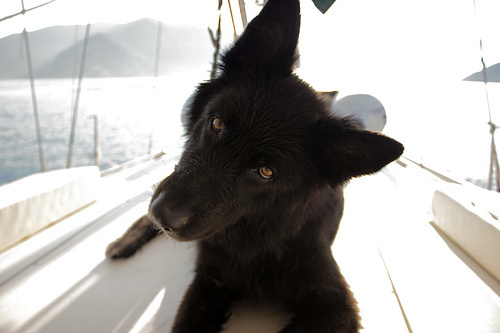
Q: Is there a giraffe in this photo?
A: No, there are no giraffes.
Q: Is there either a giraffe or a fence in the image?
A: No, there are no giraffes or fences.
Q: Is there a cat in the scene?
A: No, there are no cats.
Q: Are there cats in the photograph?
A: No, there are no cats.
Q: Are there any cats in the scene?
A: No, there are no cats.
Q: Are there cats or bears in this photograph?
A: No, there are no cats or bears.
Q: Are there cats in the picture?
A: No, there are no cats.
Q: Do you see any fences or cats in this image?
A: No, there are no cats or fences.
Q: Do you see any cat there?
A: No, there are no cats.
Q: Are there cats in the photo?
A: No, there are no cats.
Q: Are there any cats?
A: No, there are no cats.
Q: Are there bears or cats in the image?
A: No, there are no cats or bears.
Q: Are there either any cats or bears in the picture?
A: No, there are no cats or bears.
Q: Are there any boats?
A: Yes, there is a boat.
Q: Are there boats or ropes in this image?
A: Yes, there is a boat.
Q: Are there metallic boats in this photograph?
A: Yes, there is a metal boat.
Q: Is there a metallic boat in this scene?
A: Yes, there is a metal boat.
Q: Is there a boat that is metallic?
A: Yes, there is a boat that is metallic.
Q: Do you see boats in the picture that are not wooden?
A: Yes, there is a metallic boat.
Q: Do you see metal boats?
A: Yes, there is a boat that is made of metal.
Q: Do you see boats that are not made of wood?
A: Yes, there is a boat that is made of metal.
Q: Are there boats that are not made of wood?
A: Yes, there is a boat that is made of metal.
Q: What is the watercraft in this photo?
A: The watercraft is a boat.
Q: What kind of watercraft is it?
A: The watercraft is a boat.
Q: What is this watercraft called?
A: This is a boat.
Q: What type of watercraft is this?
A: This is a boat.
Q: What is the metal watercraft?
A: The watercraft is a boat.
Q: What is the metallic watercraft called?
A: The watercraft is a boat.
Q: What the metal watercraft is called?
A: The watercraft is a boat.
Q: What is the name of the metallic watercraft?
A: The watercraft is a boat.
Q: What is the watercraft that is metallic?
A: The watercraft is a boat.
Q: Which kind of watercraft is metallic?
A: The watercraft is a boat.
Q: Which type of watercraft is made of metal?
A: The watercraft is a boat.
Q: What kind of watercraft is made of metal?
A: The watercraft is a boat.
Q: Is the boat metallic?
A: Yes, the boat is metallic.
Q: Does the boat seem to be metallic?
A: Yes, the boat is metallic.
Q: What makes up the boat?
A: The boat is made of metal.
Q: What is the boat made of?
A: The boat is made of metal.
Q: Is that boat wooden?
A: No, the boat is metallic.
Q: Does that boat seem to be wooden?
A: No, the boat is metallic.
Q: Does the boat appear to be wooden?
A: No, the boat is metallic.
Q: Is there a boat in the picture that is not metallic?
A: No, there is a boat but it is metallic.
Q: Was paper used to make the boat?
A: No, the boat is made of metal.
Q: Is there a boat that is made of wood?
A: No, there is a boat but it is made of metal.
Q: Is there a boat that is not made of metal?
A: No, there is a boat but it is made of metal.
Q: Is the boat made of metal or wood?
A: The boat is made of metal.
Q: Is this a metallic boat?
A: Yes, this is a metallic boat.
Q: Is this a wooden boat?
A: No, this is a metallic boat.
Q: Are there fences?
A: No, there are no fences.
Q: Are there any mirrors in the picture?
A: No, there are no mirrors.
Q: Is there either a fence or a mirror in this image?
A: No, there are no mirrors or fences.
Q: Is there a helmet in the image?
A: No, there are no helmets.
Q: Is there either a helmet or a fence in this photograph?
A: No, there are no helmets or fences.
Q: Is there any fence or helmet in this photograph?
A: No, there are no helmets or fences.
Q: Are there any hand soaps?
A: No, there are no hand soaps.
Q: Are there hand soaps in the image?
A: No, there are no hand soaps.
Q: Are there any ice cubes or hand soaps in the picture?
A: No, there are no hand soaps or ice cubes.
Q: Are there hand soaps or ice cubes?
A: No, there are no hand soaps or ice cubes.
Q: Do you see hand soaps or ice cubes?
A: No, there are no hand soaps or ice cubes.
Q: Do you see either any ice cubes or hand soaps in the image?
A: No, there are no hand soaps or ice cubes.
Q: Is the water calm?
A: Yes, the water is calm.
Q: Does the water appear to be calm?
A: Yes, the water is calm.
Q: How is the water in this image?
A: The water is calm.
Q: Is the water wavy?
A: No, the water is calm.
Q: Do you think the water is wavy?
A: No, the water is calm.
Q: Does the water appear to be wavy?
A: No, the water is calm.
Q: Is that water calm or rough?
A: The water is calm.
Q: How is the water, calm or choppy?
A: The water is calm.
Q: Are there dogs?
A: Yes, there is a dog.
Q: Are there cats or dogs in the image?
A: Yes, there is a dog.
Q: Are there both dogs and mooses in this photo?
A: No, there is a dog but no mooses.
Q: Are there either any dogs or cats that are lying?
A: Yes, the dog is lying.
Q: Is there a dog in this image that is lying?
A: Yes, there is a dog that is lying.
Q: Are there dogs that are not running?
A: Yes, there is a dog that is lying.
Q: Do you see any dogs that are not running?
A: Yes, there is a dog that is lying .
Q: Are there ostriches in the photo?
A: No, there are no ostriches.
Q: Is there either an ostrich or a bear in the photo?
A: No, there are no ostriches or bears.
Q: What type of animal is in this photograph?
A: The animal is a dog.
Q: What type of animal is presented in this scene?
A: The animal is a dog.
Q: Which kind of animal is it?
A: The animal is a dog.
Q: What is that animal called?
A: This is a dog.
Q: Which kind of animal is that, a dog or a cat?
A: This is a dog.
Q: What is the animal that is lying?
A: The animal is a dog.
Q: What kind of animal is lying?
A: The animal is a dog.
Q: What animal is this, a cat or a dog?
A: This is a dog.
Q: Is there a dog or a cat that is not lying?
A: No, there is a dog but it is lying.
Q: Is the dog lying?
A: Yes, the dog is lying.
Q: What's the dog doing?
A: The dog is lying.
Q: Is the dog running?
A: No, the dog is lying.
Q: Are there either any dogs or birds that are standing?
A: No, there is a dog but it is lying.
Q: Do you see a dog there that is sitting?
A: No, there is a dog but it is lying.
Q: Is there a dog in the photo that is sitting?
A: No, there is a dog but it is lying.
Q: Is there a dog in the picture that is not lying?
A: No, there is a dog but it is lying.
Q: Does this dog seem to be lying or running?
A: The dog is lying.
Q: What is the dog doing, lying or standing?
A: The dog is lying.